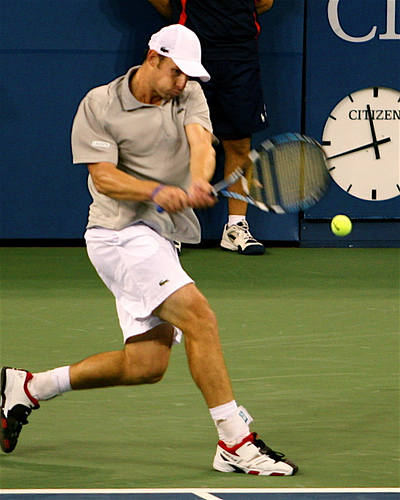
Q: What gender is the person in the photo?
A: Male.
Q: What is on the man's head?
A: White hat.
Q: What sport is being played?
A: Tennis.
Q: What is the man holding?
A: A tennis racket.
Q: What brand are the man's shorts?
A: Nike.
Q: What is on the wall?
A: A clock face.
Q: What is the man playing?
A: Tennis.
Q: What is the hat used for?
A: Sun protection.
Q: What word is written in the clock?
A: Citizen.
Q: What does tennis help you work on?
A: Lateral movement.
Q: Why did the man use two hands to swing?
A: Backhand hit.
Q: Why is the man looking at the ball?
A: To hit it.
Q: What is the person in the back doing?
A: Watching the game.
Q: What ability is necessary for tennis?
A: Hand-eye coordination.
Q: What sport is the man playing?
A: Tennis.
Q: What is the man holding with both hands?
A: A tennis racket.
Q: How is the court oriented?
A: It's on a smooth surface.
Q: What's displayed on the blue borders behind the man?
A: A clock.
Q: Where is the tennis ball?
A: Near the racket.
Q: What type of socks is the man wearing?
A: High top.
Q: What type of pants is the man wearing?
A: Short and white pants.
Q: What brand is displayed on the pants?
A: Nike.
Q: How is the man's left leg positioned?
A: It's bent 90 degrees.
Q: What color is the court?
A: Blue.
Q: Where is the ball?
A: In front of him.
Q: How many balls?
A: 1.